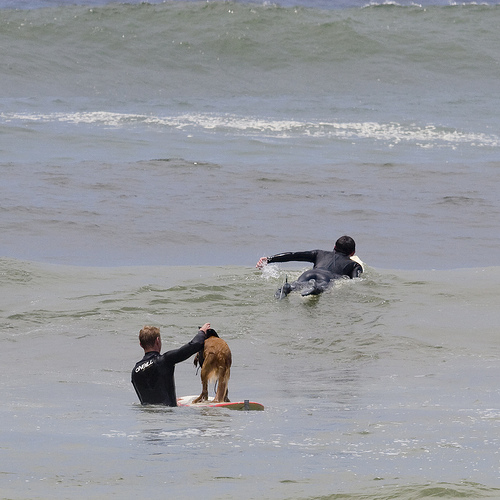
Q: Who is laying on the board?
A: A man.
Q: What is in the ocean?
A: Waves.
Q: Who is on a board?
A: A dog.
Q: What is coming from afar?
A: A small wave.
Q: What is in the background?
A: The ocean.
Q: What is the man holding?
A: A surfboard.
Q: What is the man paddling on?
A: A surfboard.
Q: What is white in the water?
A: Breaking wave.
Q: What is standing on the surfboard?
A: Dog.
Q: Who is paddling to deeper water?
A: Man on right.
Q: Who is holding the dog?
A: Man on left.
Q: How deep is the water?
A: Waist deep.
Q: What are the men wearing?
A: Wetsuits.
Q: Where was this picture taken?
A: Beach.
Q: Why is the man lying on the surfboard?
A: Paddling.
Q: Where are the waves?
A: Upper part of picture.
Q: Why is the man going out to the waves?
A: To surf.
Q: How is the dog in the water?
A: On surfboard.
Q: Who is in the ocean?
A: Two men and a dog.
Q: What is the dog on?
A: Surf board.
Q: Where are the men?
A: Ocean.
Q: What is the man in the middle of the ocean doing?
A: Swimming.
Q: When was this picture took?
A: Daytime.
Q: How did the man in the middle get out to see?
A: By swimming.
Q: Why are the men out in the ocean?
A: Surfing.